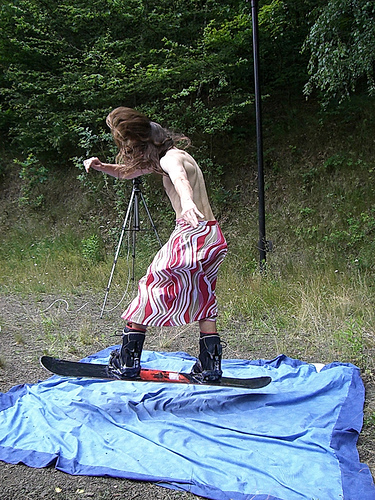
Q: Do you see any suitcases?
A: No, there are no suitcases.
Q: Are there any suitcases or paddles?
A: No, there are no suitcases or paddles.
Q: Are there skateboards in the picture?
A: Yes, there is a skateboard.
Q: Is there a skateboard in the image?
A: Yes, there is a skateboard.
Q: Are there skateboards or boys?
A: Yes, there is a skateboard.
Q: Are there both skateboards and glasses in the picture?
A: No, there is a skateboard but no glasses.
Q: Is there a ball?
A: No, there are no balls.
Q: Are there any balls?
A: No, there are no balls.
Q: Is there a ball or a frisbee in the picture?
A: No, there are no balls or frisbees.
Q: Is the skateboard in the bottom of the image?
A: Yes, the skateboard is in the bottom of the image.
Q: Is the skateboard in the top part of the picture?
A: No, the skateboard is in the bottom of the image.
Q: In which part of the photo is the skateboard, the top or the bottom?
A: The skateboard is in the bottom of the image.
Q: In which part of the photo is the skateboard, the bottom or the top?
A: The skateboard is in the bottom of the image.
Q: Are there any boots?
A: Yes, there are boots.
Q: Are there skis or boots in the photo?
A: Yes, there are boots.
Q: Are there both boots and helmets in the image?
A: No, there are boots but no helmets.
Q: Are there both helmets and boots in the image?
A: No, there are boots but no helmets.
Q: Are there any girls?
A: No, there are no girls.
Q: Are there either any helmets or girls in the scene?
A: No, there are no girls or helmets.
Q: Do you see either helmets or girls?
A: No, there are no girls or helmets.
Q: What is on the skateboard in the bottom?
A: The boots are on the skateboard.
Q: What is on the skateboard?
A: The boots are on the skateboard.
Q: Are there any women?
A: No, there are no women.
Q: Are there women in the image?
A: No, there are no women.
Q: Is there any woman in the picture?
A: No, there are no women.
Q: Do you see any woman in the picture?
A: No, there are no women.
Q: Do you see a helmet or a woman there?
A: No, there are no women or helmets.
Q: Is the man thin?
A: Yes, the man is thin.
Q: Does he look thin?
A: Yes, the man is thin.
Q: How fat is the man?
A: The man is thin.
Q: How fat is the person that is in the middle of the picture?
A: The man is thin.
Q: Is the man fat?
A: No, the man is thin.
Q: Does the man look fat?
A: No, the man is thin.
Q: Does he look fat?
A: No, the man is thin.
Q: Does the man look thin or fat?
A: The man is thin.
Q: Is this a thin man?
A: Yes, this is a thin man.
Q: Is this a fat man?
A: No, this is a thin man.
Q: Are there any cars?
A: No, there are no cars.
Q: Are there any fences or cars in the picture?
A: No, there are no cars or fences.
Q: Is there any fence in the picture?
A: No, there are no fences.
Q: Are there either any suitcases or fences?
A: No, there are no fences or suitcases.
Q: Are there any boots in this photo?
A: Yes, there are boots.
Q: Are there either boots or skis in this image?
A: Yes, there are boots.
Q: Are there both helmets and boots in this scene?
A: No, there are boots but no helmets.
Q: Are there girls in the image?
A: No, there are no girls.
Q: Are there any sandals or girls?
A: No, there are no girls or sandals.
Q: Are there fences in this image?
A: No, there are no fences.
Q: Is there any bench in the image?
A: No, there are no benches.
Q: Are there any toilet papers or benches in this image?
A: No, there are no benches or toilet papers.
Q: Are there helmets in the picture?
A: No, there are no helmets.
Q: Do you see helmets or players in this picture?
A: No, there are no helmets or players.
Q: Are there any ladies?
A: No, there are no ladies.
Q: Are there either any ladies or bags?
A: No, there are no ladies or bags.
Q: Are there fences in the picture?
A: No, there are no fences.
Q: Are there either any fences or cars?
A: No, there are no fences or cars.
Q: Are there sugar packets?
A: No, there are no sugar packets.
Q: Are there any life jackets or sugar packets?
A: No, there are no sugar packets or life jackets.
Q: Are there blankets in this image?
A: Yes, there is a blanket.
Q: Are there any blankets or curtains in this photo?
A: Yes, there is a blanket.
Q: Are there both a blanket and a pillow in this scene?
A: No, there is a blanket but no pillows.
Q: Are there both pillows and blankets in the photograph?
A: No, there is a blanket but no pillows.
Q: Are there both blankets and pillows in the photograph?
A: No, there is a blanket but no pillows.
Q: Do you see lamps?
A: No, there are no lamps.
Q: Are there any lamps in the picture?
A: No, there are no lamps.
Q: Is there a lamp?
A: No, there are no lamps.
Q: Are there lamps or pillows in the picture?
A: No, there are no lamps or pillows.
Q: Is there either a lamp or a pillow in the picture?
A: No, there are no lamps or pillows.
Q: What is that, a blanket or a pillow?
A: That is a blanket.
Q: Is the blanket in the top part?
A: No, the blanket is in the bottom of the image.